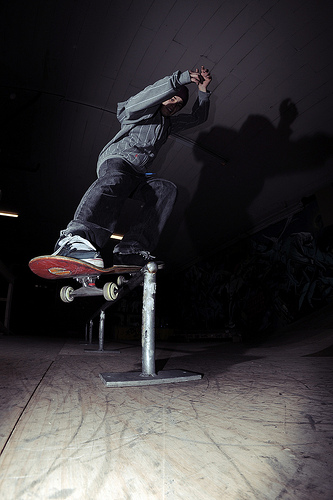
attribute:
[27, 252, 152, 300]
skateboard — red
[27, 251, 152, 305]
board — red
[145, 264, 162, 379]
leg — grey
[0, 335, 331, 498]
skating ground — rough 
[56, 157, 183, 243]
pants — black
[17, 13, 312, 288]
ground — rough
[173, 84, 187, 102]
hat — black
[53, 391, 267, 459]
ground — concrete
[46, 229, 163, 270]
shoes — black, white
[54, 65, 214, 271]
man — shadow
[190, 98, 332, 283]
shadow — large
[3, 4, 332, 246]
ceiling — wooden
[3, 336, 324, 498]
ground — rough, for skating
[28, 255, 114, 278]
bottom — red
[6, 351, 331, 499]
floor — light brown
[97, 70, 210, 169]
jacket — pinstriped, white, grey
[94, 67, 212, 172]
stripes — gray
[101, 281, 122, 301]
wheel — white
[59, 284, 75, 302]
wheel — white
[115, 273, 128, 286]
wheel — white